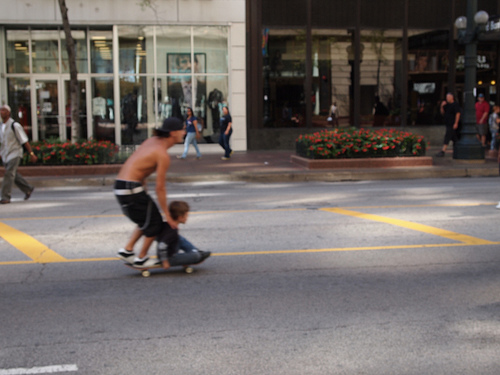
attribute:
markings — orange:
[325, 193, 469, 267]